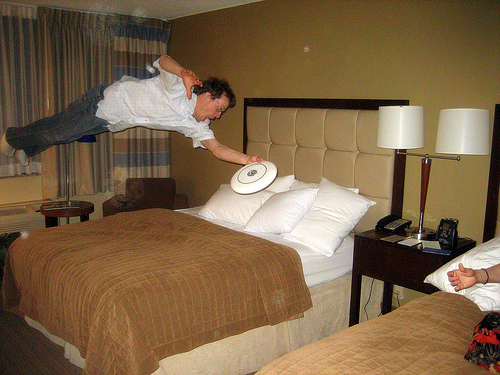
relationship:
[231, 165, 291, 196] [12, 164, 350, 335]
frisbee above bed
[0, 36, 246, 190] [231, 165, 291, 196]
man with frisbee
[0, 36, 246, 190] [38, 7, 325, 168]
man in air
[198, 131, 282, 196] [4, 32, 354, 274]
hand in foreground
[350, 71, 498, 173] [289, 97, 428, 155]
lamp has shades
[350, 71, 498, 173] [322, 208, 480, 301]
lamp on table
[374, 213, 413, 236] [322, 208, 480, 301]
phone on table